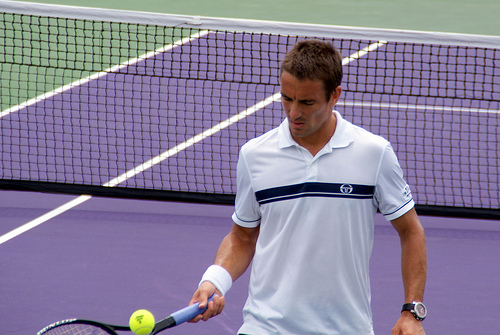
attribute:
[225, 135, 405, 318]
shirt — white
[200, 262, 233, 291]
wristband — white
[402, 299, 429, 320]
watch — black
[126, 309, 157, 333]
tennis ball — yellow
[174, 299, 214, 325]
tape — blue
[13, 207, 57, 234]
line — white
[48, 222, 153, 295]
court — purple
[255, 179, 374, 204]
stripe — black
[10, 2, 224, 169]
net — white, tennis net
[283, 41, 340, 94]
hair — short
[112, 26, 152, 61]
string — black